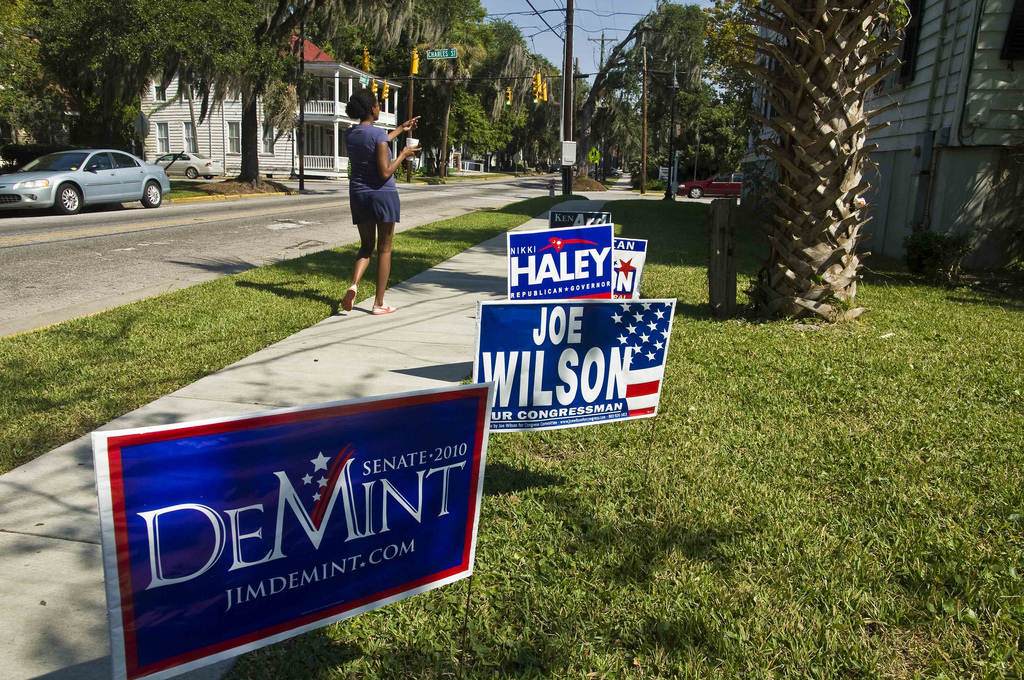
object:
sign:
[474, 281, 676, 433]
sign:
[506, 222, 614, 302]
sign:
[612, 237, 648, 300]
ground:
[0, 169, 1024, 678]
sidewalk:
[0, 177, 626, 676]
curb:
[170, 190, 303, 203]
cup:
[405, 137, 420, 160]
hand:
[400, 145, 424, 158]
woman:
[340, 91, 423, 315]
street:
[0, 166, 623, 347]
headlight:
[21, 178, 49, 188]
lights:
[409, 45, 421, 75]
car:
[146, 151, 225, 179]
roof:
[276, 35, 336, 62]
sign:
[426, 49, 458, 59]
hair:
[346, 90, 375, 118]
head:
[345, 90, 380, 121]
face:
[374, 100, 380, 119]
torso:
[342, 123, 398, 193]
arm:
[376, 143, 406, 181]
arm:
[388, 125, 402, 141]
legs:
[375, 220, 394, 304]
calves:
[353, 247, 372, 285]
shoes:
[371, 303, 400, 314]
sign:
[87, 377, 492, 680]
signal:
[504, 87, 512, 105]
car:
[678, 171, 745, 198]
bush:
[904, 213, 999, 291]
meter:
[919, 148, 948, 232]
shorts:
[349, 191, 402, 225]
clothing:
[344, 124, 403, 225]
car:
[2, 145, 174, 216]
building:
[137, 21, 402, 178]